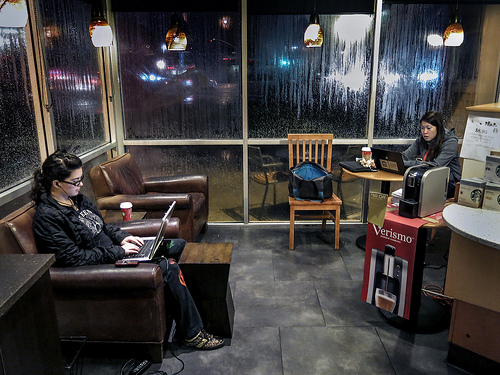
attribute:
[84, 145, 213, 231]
chair — brown, leather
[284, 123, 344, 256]
chair — brown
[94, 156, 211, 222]
chair — red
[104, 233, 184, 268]
lap — woman's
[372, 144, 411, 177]
laptop — black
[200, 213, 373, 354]
floor — stone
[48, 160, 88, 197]
face — girl's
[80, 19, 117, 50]
light — bright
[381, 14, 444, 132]
glass — window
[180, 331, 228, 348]
shoes — black, tan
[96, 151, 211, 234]
chair — brown, leather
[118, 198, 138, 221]
cup — paper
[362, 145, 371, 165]
cup — paper, coffee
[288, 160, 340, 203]
bag — open, black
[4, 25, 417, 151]
rain — pouring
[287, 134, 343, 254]
chair — wooden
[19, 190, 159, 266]
black jacket — black 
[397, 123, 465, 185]
grey jacket — grey 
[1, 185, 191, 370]
leather chair — large , brown , leather 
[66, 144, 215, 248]
leather chair — large , brown , leather 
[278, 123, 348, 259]
wooden chair — light colored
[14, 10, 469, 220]
glass windows — glass 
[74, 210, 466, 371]
grey tile — grey 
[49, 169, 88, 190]
black glasses — black 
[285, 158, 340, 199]
bag — black , blue 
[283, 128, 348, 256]
wooden chair — wooden 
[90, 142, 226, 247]
love seat — leather 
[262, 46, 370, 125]
window — wet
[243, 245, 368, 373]
tile formation — brick set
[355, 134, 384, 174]
coffee cup — red